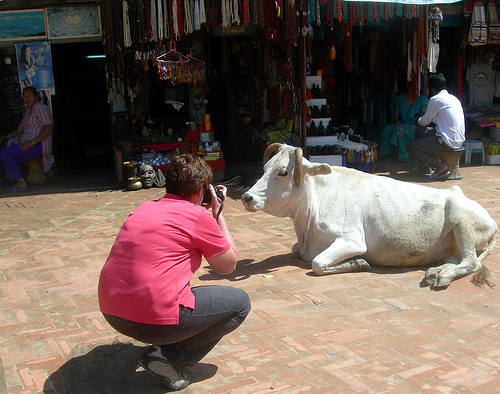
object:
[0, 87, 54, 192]
lady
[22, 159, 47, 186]
stool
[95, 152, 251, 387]
man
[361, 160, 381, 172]
ground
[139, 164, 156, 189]
mask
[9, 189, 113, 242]
ground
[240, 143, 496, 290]
animal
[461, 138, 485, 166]
foot stools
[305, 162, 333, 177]
ear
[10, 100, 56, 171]
shirt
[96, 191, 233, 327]
shirt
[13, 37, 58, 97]
artwork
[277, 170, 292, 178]
eye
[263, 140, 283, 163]
horns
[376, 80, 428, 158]
woman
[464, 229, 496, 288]
tail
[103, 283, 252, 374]
pants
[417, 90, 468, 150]
shirt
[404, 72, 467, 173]
man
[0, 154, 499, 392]
sidewalk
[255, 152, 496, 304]
ground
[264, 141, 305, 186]
inward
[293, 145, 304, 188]
horns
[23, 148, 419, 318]
picture